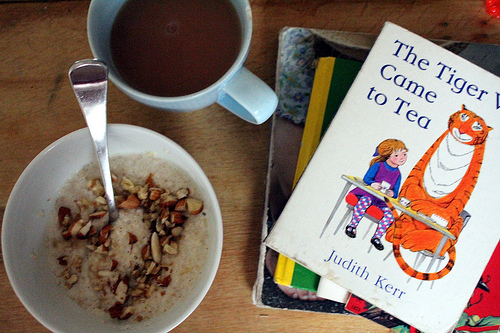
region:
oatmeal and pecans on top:
[44, 150, 219, 325]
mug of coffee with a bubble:
[77, 2, 297, 117]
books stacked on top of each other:
[233, 14, 492, 331]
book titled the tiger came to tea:
[362, 28, 496, 175]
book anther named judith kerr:
[314, 232, 416, 314]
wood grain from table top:
[212, 128, 262, 180]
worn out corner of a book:
[261, 10, 359, 65]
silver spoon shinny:
[83, 54, 115, 221]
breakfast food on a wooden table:
[18, 6, 309, 331]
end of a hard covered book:
[266, 236, 316, 305]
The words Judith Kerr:
[319, 236, 427, 321]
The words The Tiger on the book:
[397, 31, 482, 115]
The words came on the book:
[376, 51, 447, 113]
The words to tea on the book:
[360, 83, 434, 127]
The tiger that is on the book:
[392, 82, 473, 269]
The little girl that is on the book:
[349, 122, 417, 240]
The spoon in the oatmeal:
[59, 55, 146, 227]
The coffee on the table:
[49, 5, 269, 142]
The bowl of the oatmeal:
[23, 123, 220, 330]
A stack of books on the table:
[267, 48, 498, 329]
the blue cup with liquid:
[85, 0, 279, 126]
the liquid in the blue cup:
[107, 0, 239, 96]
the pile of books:
[251, 20, 498, 332]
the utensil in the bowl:
[67, 58, 117, 218]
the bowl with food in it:
[0, 122, 222, 332]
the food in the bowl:
[42, 148, 207, 323]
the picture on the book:
[319, 103, 492, 291]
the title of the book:
[367, 38, 499, 129]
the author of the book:
[323, 248, 406, 298]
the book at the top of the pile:
[262, 21, 499, 331]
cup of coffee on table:
[74, 0, 292, 142]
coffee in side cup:
[85, 0, 284, 126]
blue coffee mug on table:
[85, 0, 285, 136]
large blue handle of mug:
[220, 73, 277, 133]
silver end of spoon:
[61, 56, 127, 222]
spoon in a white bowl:
[0, 75, 237, 332]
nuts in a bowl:
[121, 183, 196, 261]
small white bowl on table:
[0, 120, 235, 309]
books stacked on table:
[278, 30, 491, 331]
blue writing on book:
[363, 26, 489, 134]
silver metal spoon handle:
[57, 54, 124, 221]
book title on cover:
[360, 34, 497, 131]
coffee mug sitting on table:
[81, 0, 276, 138]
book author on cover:
[317, 244, 414, 297]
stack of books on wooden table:
[246, 26, 498, 327]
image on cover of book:
[319, 98, 493, 285]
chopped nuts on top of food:
[139, 180, 195, 248]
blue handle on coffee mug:
[216, 69, 287, 124]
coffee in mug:
[107, 2, 244, 94]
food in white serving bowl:
[5, 126, 237, 331]